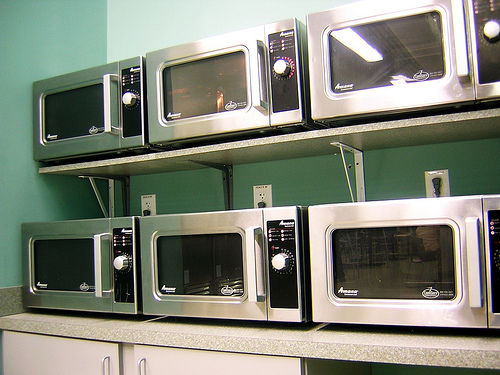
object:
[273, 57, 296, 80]
red numbers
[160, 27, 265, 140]
light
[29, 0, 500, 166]
oven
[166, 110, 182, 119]
white letters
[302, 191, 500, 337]
oven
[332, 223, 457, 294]
reflection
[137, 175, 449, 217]
cords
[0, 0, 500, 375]
wall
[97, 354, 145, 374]
cabinet handles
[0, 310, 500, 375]
counter top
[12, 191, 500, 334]
microwave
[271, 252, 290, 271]
knob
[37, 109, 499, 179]
shelf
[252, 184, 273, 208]
electrical outlet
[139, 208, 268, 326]
microwave door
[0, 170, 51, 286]
green paint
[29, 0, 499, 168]
microwaves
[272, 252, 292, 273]
silver knob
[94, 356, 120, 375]
handle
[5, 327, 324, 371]
cabinet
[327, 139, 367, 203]
latches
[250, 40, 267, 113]
door handle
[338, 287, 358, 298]
white writing